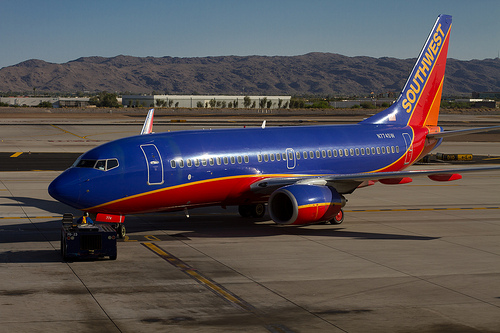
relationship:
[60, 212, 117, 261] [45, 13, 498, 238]
vehicle used to pushed a plane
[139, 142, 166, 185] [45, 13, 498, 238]
cabin door of plane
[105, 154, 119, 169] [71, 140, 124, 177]
window to cockpit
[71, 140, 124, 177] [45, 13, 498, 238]
cockpit on a plane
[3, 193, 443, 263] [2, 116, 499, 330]
shadow on tarmac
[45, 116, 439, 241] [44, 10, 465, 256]
paint on plane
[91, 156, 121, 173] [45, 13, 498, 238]
window on plane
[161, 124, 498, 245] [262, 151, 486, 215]
stripe on wing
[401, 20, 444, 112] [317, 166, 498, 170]
word on wing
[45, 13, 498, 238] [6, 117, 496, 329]
plane on runway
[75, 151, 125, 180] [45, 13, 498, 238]
cockpit of plane